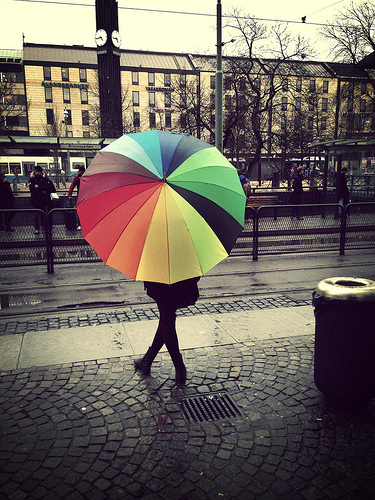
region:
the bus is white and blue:
[2, 146, 102, 200]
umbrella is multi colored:
[44, 119, 272, 305]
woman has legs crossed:
[127, 304, 200, 383]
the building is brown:
[25, 43, 334, 136]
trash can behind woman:
[287, 240, 373, 405]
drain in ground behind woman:
[140, 378, 264, 439]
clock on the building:
[86, 20, 132, 62]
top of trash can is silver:
[307, 256, 367, 302]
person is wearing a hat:
[16, 154, 66, 186]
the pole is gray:
[199, 2, 234, 154]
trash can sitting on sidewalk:
[304, 262, 374, 415]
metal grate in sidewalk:
[176, 382, 248, 440]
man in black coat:
[19, 161, 67, 244]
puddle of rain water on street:
[3, 282, 57, 317]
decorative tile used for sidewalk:
[15, 376, 170, 491]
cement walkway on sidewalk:
[15, 295, 305, 367]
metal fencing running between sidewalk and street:
[22, 201, 355, 279]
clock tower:
[88, 2, 141, 189]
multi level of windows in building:
[30, 53, 372, 157]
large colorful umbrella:
[69, 108, 260, 299]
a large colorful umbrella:
[66, 123, 259, 290]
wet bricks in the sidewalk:
[57, 380, 136, 466]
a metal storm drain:
[175, 391, 251, 424]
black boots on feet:
[137, 342, 194, 384]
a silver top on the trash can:
[319, 271, 373, 299]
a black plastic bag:
[312, 291, 323, 311]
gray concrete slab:
[19, 325, 133, 358]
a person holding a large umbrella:
[72, 121, 284, 430]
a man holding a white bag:
[21, 161, 58, 211]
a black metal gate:
[19, 207, 90, 260]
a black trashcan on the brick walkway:
[318, 276, 373, 298]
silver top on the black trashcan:
[316, 276, 374, 296]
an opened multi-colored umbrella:
[77, 129, 246, 286]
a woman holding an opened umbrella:
[73, 128, 247, 385]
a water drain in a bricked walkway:
[176, 391, 244, 426]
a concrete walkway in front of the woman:
[1, 305, 312, 371]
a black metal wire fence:
[1, 201, 374, 272]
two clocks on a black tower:
[94, 29, 121, 48]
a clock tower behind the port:
[94, 0, 122, 136]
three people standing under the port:
[0, 164, 85, 233]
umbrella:
[45, 115, 257, 295]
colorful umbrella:
[76, 137, 263, 272]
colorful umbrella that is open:
[72, 126, 240, 277]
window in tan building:
[39, 66, 58, 81]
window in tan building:
[42, 80, 56, 104]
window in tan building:
[76, 65, 89, 84]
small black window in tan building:
[68, 77, 87, 107]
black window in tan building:
[196, 65, 217, 93]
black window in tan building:
[143, 70, 151, 87]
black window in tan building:
[127, 65, 144, 92]